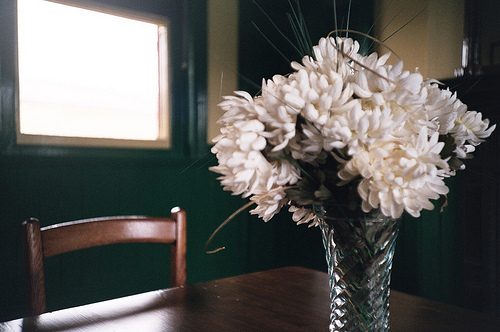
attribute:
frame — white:
[12, 0, 171, 146]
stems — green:
[290, 158, 362, 217]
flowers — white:
[209, 35, 496, 224]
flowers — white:
[211, 32, 472, 198]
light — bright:
[53, 40, 175, 148]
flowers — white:
[215, 36, 489, 213]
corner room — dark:
[238, 1, 378, 99]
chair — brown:
[16, 205, 186, 314]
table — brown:
[0, 263, 499, 329]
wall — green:
[4, 171, 216, 320]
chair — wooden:
[36, 212, 224, 307]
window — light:
[13, 0, 169, 147]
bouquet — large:
[216, 35, 499, 217]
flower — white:
[367, 151, 445, 212]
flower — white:
[456, 111, 492, 146]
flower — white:
[220, 92, 257, 122]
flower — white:
[213, 151, 271, 197]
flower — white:
[251, 189, 288, 220]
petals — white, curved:
[404, 187, 419, 216]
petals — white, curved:
[410, 157, 427, 172]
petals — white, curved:
[373, 173, 384, 209]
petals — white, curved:
[328, 105, 368, 125]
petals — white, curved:
[370, 112, 405, 129]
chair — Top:
[46, 200, 121, 243]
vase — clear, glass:
[312, 202, 405, 330]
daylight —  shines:
[50, 7, 163, 137]